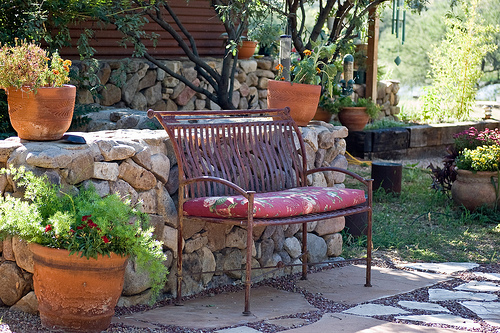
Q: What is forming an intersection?
A: Two low stone walls.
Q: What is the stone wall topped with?
A: Wood paneled wall.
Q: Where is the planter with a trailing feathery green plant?
A: In front of the wall.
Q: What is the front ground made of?
A: Large and small flat stones.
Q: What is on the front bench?
A: Red cushion with floral pattern.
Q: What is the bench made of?
A: Rusted metal.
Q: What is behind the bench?
A: Stone wall.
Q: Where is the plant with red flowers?
A: Clay pot in front.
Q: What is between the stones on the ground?
A: Gray gravel.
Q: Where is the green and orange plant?
A: Right side of front stone wall.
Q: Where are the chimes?
A: Next to wooden pole in right background.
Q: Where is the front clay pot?
A: On top of gray gravel.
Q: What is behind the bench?
A: A rock wall.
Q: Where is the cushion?
A: On the bench.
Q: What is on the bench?
A: A cushion.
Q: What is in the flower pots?
A: Flowering plants.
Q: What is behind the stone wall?
A: A tree.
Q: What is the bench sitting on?
A: A stone walkway.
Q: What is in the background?
A: A house.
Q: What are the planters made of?
A: Clay.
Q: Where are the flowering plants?
A: In the planters.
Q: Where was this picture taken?
A: A garden wall.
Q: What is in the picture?
A: A wall and bench.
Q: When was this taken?
A: Daytime.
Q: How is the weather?
A: Sunny.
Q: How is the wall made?
A: Of stone.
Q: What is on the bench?
A: A pillow.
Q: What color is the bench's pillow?
A: Red.